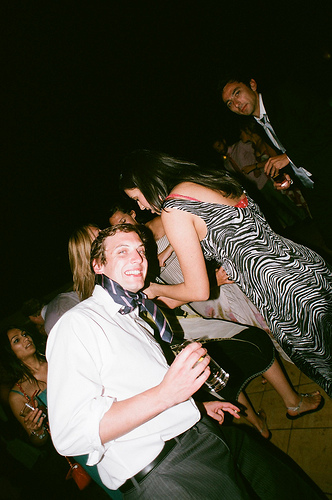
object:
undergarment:
[164, 192, 250, 208]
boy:
[45, 223, 326, 498]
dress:
[11, 387, 126, 499]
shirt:
[45, 283, 202, 491]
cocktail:
[20, 400, 46, 418]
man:
[216, 67, 332, 249]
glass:
[177, 336, 230, 392]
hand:
[163, 341, 212, 403]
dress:
[161, 195, 331, 398]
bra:
[165, 193, 200, 202]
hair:
[0, 330, 41, 393]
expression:
[10, 328, 35, 353]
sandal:
[285, 392, 323, 420]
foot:
[287, 390, 321, 416]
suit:
[252, 81, 331, 249]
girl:
[118, 148, 332, 395]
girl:
[0, 325, 126, 497]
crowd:
[0, 0, 331, 498]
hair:
[119, 147, 245, 212]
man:
[209, 129, 307, 229]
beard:
[221, 142, 229, 154]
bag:
[68, 461, 91, 490]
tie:
[94, 272, 175, 344]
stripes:
[152, 301, 157, 322]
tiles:
[286, 427, 331, 494]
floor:
[233, 349, 332, 497]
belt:
[118, 430, 184, 492]